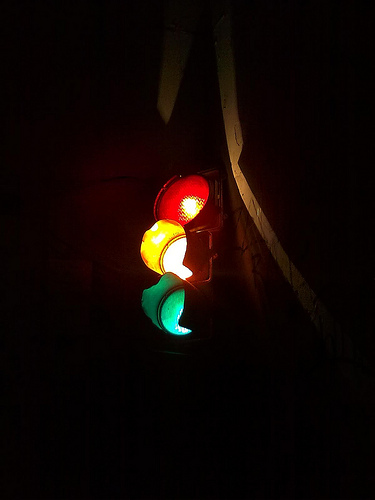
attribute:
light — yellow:
[139, 225, 196, 271]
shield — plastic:
[158, 175, 207, 222]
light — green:
[144, 277, 201, 333]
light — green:
[130, 167, 262, 343]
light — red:
[152, 169, 215, 228]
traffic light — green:
[136, 164, 228, 352]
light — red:
[166, 179, 207, 227]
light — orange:
[159, 227, 196, 280]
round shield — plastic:
[140, 271, 192, 334]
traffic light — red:
[154, 170, 211, 227]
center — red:
[175, 189, 202, 229]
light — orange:
[128, 216, 226, 282]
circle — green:
[156, 173, 209, 227]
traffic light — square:
[147, 170, 212, 231]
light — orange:
[113, 152, 220, 374]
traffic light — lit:
[135, 167, 230, 369]